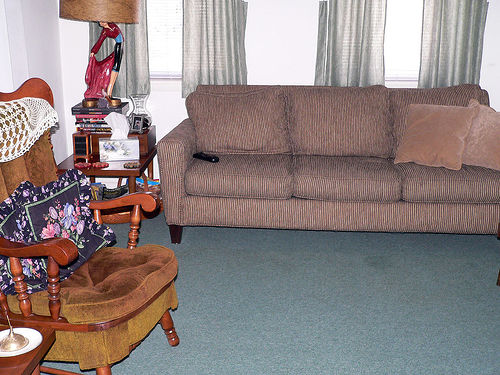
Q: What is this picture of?
A: Living room.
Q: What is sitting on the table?
A: Box of tissues.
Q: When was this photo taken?
A: Daytime.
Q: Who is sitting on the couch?
A: No one.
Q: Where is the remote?
A: On the couch.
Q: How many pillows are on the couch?
A: 2.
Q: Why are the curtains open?
A: To let light in.